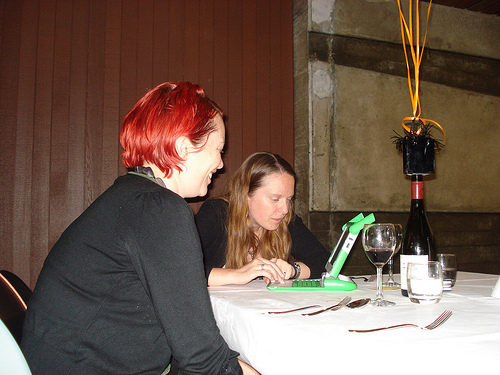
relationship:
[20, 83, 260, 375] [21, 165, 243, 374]
lady wearing black shirt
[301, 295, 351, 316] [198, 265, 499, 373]
utensil lying on top of table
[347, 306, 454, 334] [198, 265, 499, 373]
fork lying on top of table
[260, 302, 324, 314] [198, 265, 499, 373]
utensil lying on top of table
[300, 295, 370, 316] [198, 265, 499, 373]
utensil lying on top of table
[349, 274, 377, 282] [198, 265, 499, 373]
utensil lying on top of table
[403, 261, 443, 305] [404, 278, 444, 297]
cup containing water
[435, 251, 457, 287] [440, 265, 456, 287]
cup containing water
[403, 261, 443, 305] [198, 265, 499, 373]
cup sitting on top of table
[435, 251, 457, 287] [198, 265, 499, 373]
cup sitting on top of table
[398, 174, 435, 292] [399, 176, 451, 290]
bottle containing wine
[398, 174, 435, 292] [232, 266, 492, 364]
bottle standing on top of table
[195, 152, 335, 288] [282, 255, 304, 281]
girl wearing watch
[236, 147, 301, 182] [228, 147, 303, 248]
hair belonging to woman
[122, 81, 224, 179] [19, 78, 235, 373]
red hair belonging to woman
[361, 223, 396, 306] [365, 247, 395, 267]
glasses containing wine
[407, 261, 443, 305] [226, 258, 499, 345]
cup sitting on top of table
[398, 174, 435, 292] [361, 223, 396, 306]
bottle next to glasses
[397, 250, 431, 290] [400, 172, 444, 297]
label on bottle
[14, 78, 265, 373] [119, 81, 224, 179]
lady with red hair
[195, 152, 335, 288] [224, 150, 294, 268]
girl with hair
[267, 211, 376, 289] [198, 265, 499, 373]
computer on table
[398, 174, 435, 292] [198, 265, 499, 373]
bottle on table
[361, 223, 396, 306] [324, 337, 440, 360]
glasses on table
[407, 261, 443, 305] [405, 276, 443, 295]
cup contains water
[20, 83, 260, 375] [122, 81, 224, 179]
lady with red hair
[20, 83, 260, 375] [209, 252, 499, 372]
lady sitting at a table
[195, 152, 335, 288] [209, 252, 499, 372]
girl sitting at a table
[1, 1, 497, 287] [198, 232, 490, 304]
wall near table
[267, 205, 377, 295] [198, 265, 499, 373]
computer on table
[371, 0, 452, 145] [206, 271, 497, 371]
strings on table